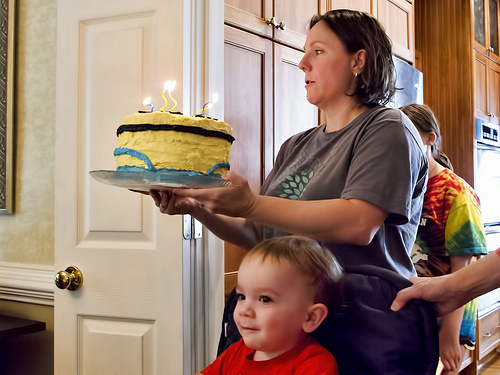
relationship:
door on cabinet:
[228, 18, 304, 194] [234, 32, 346, 201]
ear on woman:
[345, 47, 369, 78] [283, 21, 433, 367]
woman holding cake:
[283, 21, 433, 367] [120, 108, 239, 178]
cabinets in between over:
[416, 16, 472, 150] [472, 106, 499, 158]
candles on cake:
[133, 66, 260, 142] [120, 108, 239, 178]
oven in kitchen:
[460, 117, 499, 171] [169, 38, 499, 365]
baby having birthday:
[230, 233, 349, 365] [152, 49, 477, 356]